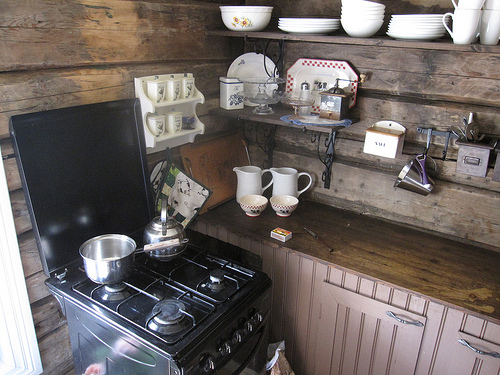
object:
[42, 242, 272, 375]
stove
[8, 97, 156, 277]
lid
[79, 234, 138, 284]
pan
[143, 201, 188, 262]
kettle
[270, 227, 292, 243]
matches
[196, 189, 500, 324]
counter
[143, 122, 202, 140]
shelf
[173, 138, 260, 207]
tray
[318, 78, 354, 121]
sifter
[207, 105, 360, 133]
shelf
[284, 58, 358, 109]
plate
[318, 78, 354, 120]
coffee grinder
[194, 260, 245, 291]
burner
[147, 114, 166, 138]
pot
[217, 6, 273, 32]
bowl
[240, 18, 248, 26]
flowers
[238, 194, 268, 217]
tea cup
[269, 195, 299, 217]
tea cup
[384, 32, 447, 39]
plates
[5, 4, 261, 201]
wall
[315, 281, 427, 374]
cabinet door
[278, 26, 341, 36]
dishes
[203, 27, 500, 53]
shelf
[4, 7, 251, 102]
logs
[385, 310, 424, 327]
handle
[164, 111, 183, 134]
pot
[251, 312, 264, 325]
knob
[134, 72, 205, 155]
rack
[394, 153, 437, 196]
cup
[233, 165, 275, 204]
pitcher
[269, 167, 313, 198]
pitcher